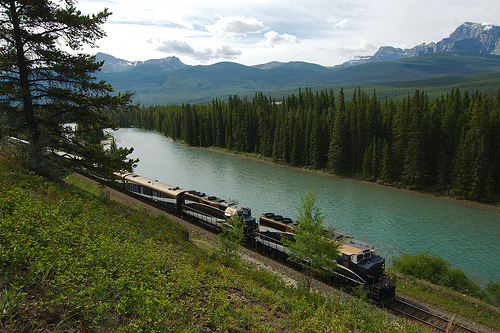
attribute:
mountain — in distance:
[85, 50, 280, 100]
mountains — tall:
[86, 17, 499, 70]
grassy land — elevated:
[0, 162, 428, 331]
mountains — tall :
[1, 19, 499, 104]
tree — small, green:
[279, 186, 347, 291]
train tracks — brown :
[387, 298, 476, 331]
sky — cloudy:
[72, 3, 496, 56]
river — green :
[117, 121, 494, 273]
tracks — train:
[386, 281, 448, 329]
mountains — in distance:
[95, 15, 499, 96]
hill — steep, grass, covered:
[3, 137, 395, 328]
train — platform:
[8, 132, 396, 316]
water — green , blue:
[182, 144, 472, 291]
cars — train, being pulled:
[117, 170, 254, 241]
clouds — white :
[139, 2, 291, 52]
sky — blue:
[10, 1, 496, 56]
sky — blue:
[121, 10, 406, 46]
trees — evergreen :
[122, 87, 494, 204]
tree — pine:
[1, 2, 125, 186]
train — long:
[2, 128, 482, 318]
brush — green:
[383, 243, 479, 301]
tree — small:
[275, 174, 339, 297]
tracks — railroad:
[255, 219, 475, 331]